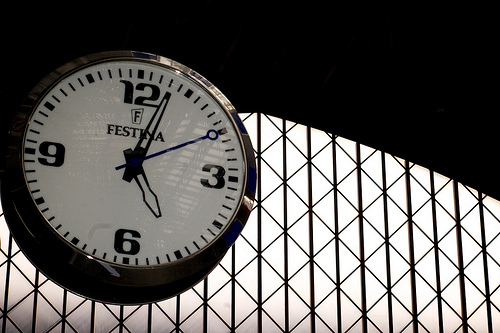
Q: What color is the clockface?
A: White.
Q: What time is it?
A: 5:03.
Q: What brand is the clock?
A: Festina.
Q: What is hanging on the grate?
A: A clock.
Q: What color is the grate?
A: Black.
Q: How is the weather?
A: Overcast.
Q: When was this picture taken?
A: Daytime.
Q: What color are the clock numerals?
A: Black.